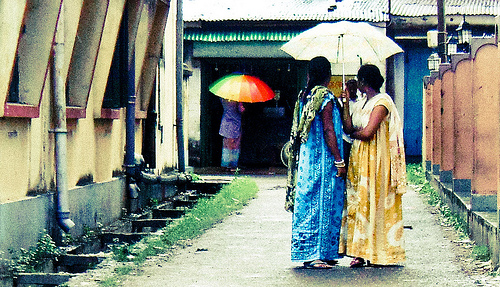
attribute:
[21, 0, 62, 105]
column — tan 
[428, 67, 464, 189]
column — tan 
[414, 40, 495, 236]
column — tan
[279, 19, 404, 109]
umbrella — white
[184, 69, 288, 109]
umbrella — opened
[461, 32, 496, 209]
column — tan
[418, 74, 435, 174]
column — tan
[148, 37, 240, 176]
column — tan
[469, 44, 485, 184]
column — tan